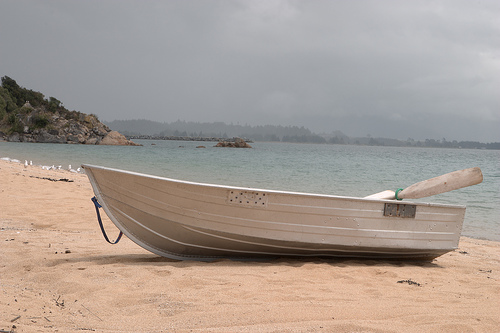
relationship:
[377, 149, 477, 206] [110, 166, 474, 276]
oar out of boat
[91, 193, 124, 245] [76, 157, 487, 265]
rope handing down from aluminum canoe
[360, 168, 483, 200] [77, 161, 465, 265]
oar sticking out of boat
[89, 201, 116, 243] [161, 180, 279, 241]
rope tied to boat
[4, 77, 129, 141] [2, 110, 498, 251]
rocks into water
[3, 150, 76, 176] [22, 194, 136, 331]
seagulls on beach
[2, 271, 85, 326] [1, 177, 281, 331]
sticks in sand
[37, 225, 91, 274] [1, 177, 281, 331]
stuff in sand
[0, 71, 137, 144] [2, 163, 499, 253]
hillside by waters edge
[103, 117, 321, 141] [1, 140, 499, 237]
tree line by ocean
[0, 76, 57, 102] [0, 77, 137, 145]
trees on hillside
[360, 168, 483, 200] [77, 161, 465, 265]
oar in boat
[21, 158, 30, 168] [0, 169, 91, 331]
seagull on beach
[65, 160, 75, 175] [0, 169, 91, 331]
seagull on beach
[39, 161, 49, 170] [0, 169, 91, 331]
seagull on beach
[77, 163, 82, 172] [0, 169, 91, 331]
seagull on beach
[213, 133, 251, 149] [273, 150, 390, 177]
small island in water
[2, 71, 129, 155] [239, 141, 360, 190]
land extends into water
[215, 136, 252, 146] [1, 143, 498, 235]
outcropping in water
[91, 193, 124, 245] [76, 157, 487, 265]
rope on aluminum canoe